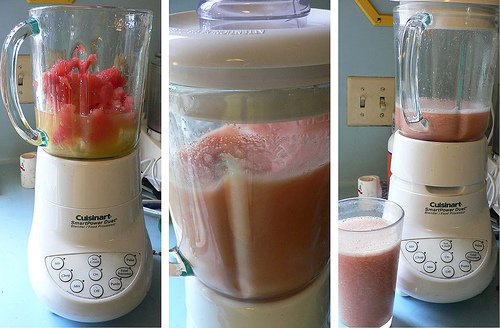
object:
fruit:
[35, 45, 141, 157]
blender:
[0, 2, 162, 328]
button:
[85, 251, 103, 269]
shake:
[337, 215, 404, 327]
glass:
[338, 193, 409, 328]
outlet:
[345, 74, 396, 131]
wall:
[337, 1, 409, 203]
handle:
[0, 15, 53, 147]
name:
[65, 209, 123, 234]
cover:
[164, 0, 332, 87]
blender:
[166, 0, 332, 328]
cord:
[138, 153, 168, 216]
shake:
[391, 96, 490, 141]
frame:
[353, 1, 393, 29]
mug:
[357, 174, 385, 201]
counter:
[0, 0, 160, 327]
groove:
[168, 109, 337, 301]